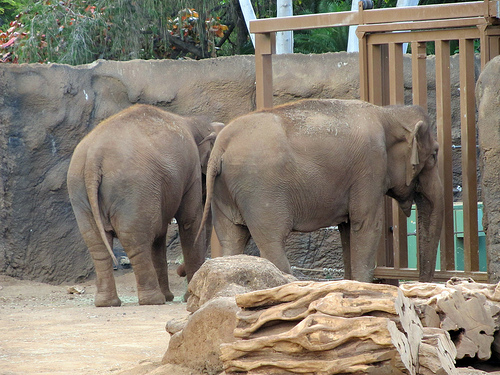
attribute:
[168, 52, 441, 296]
elephant — facing, brown, long, grey, standing, inside, looking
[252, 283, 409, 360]
log — fake, large, wavy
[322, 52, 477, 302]
fence — brown, storage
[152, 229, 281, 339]
rock — large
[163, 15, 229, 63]
tree — brown, white, cut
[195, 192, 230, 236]
tail — gray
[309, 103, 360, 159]
skin — gray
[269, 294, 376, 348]
plank — wooden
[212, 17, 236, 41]
fruit — orange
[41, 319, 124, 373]
sand — beige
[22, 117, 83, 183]
wall — stone, large, brown, drooping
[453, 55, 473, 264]
post — wooden